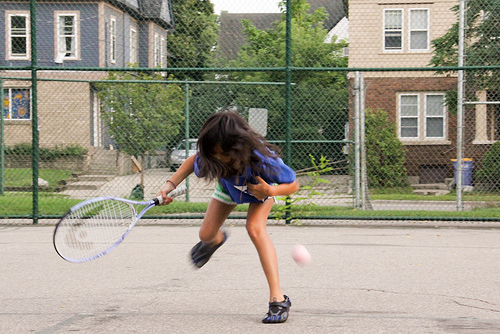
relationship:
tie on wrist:
[163, 175, 180, 197] [156, 172, 182, 205]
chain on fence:
[15, 8, 480, 233] [23, 24, 472, 211]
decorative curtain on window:
[4, 88, 27, 118] [10, 87, 29, 117]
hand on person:
[248, 174, 271, 199] [159, 110, 298, 322]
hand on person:
[136, 164, 191, 206] [183, 97, 323, 311]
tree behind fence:
[92, 66, 185, 166] [30, 8, 481, 115]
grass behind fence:
[4, 190, 498, 218] [0, 0, 499, 222]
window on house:
[54, 11, 79, 56] [4, 3, 179, 168]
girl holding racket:
[155, 111, 298, 324] [13, 151, 193, 296]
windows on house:
[385, 13, 403, 56] [343, 6, 492, 170]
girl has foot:
[155, 111, 298, 324] [259, 290, 301, 324]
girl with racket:
[155, 103, 305, 329] [44, 180, 194, 267]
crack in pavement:
[363, 282, 498, 312] [1, 216, 498, 328]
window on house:
[391, 90, 450, 147] [343, 2, 499, 193]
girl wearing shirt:
[155, 111, 298, 324] [253, 158, 281, 172]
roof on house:
[217, 7, 284, 57] [188, 2, 348, 176]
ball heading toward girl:
[287, 233, 316, 273] [158, 76, 343, 325]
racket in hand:
[52, 187, 202, 274] [151, 186, 181, 211]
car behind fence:
[165, 134, 204, 170] [67, 61, 394, 211]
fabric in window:
[6, 84, 33, 120] [5, 84, 38, 124]